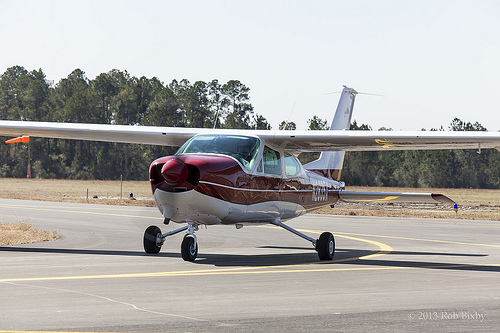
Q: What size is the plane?
A: Small.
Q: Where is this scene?
A: Runway.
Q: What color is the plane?
A: Red and white.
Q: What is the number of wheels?
A: 3.